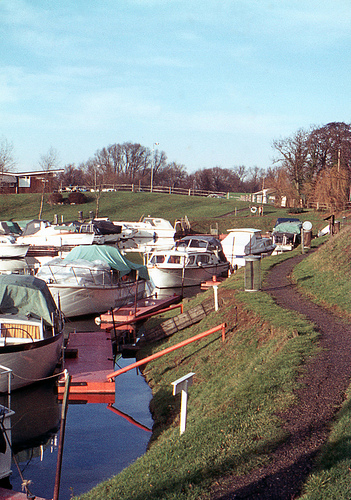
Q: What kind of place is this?
A: It is a harbor.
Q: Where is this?
A: This is at the harbor.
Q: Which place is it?
A: It is a harbor.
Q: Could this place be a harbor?
A: Yes, it is a harbor.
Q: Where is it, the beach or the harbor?
A: It is the harbor.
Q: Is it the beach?
A: No, it is the harbor.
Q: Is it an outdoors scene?
A: Yes, it is outdoors.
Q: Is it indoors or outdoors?
A: It is outdoors.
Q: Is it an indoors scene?
A: No, it is outdoors.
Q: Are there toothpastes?
A: No, there are no toothpastes.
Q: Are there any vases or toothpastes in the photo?
A: No, there are no toothpastes or vases.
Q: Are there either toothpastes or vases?
A: No, there are no toothpastes or vases.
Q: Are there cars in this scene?
A: No, there are no cars.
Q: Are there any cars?
A: No, there are no cars.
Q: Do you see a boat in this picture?
A: Yes, there is a boat.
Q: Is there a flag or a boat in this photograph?
A: Yes, there is a boat.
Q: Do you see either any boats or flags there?
A: Yes, there is a boat.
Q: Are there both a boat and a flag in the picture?
A: No, there is a boat but no flags.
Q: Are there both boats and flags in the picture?
A: No, there is a boat but no flags.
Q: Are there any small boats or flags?
A: Yes, there is a small boat.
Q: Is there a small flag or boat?
A: Yes, there is a small boat.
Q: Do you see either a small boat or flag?
A: Yes, there is a small boat.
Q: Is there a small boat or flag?
A: Yes, there is a small boat.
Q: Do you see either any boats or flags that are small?
A: Yes, the boat is small.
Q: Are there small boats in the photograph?
A: Yes, there is a small boat.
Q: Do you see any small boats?
A: Yes, there is a small boat.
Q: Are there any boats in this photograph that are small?
A: Yes, there is a boat that is small.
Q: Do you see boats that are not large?
A: Yes, there is a small boat.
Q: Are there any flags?
A: No, there are no flags.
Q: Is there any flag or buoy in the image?
A: No, there are no flags or buoys.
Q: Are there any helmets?
A: No, there are no helmets.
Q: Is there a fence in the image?
A: Yes, there is a fence.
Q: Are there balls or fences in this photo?
A: Yes, there is a fence.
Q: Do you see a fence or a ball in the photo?
A: Yes, there is a fence.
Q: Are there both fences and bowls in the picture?
A: No, there is a fence but no bowls.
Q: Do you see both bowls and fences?
A: No, there is a fence but no bowls.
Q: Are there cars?
A: No, there are no cars.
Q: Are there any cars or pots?
A: No, there are no cars or pots.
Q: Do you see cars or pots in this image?
A: No, there are no cars or pots.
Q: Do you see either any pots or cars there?
A: No, there are no cars or pots.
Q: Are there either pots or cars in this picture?
A: No, there are no cars or pots.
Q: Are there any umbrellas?
A: No, there are no umbrellas.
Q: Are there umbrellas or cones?
A: No, there are no umbrellas or cones.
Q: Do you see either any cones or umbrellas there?
A: No, there are no umbrellas or cones.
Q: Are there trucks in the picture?
A: No, there are no trucks.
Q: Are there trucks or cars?
A: No, there are no trucks or cars.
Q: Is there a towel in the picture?
A: No, there are no towels.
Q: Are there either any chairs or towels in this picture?
A: No, there are no towels or chairs.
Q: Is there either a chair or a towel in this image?
A: No, there are no towels or chairs.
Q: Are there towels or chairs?
A: No, there are no towels or chairs.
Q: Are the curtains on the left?
A: Yes, the curtains are on the left of the image.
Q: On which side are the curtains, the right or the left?
A: The curtains are on the left of the image.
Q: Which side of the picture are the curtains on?
A: The curtains are on the left of the image.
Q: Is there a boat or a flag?
A: Yes, there is a boat.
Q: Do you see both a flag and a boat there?
A: No, there is a boat but no flags.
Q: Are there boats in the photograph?
A: Yes, there is a boat.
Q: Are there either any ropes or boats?
A: Yes, there is a boat.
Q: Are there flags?
A: No, there are no flags.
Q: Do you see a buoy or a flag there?
A: No, there are no flags or buoys.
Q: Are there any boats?
A: Yes, there is a boat.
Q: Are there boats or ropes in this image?
A: Yes, there is a boat.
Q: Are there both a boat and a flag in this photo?
A: No, there is a boat but no flags.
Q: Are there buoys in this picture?
A: No, there are no buoys.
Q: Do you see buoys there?
A: No, there are no buoys.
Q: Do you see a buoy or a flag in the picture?
A: No, there are no buoys or flags.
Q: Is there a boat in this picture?
A: Yes, there is a boat.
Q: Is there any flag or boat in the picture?
A: Yes, there is a boat.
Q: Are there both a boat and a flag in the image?
A: No, there is a boat but no flags.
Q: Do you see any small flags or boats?
A: Yes, there is a small boat.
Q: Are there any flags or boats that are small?
A: Yes, the boat is small.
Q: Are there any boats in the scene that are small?
A: Yes, there is a small boat.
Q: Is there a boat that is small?
A: Yes, there is a boat that is small.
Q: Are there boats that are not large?
A: Yes, there is a small boat.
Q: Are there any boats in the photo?
A: Yes, there is a boat.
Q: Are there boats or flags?
A: Yes, there is a boat.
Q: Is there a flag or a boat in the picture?
A: Yes, there is a boat.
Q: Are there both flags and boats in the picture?
A: No, there is a boat but no flags.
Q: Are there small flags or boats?
A: Yes, there is a small boat.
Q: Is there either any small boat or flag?
A: Yes, there is a small boat.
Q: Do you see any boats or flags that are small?
A: Yes, the boat is small.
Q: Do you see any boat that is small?
A: Yes, there is a small boat.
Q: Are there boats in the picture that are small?
A: Yes, there is a boat that is small.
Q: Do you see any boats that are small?
A: Yes, there is a boat that is small.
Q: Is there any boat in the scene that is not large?
A: Yes, there is a small boat.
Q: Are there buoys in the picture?
A: No, there are no buoys.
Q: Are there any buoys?
A: No, there are no buoys.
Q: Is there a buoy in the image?
A: No, there are no buoys.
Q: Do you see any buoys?
A: No, there are no buoys.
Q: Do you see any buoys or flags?
A: No, there are no buoys or flags.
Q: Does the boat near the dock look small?
A: Yes, the boat is small.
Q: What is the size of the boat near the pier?
A: The boat is small.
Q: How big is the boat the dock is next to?
A: The boat is small.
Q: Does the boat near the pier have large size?
A: No, the boat is small.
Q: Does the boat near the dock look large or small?
A: The boat is small.